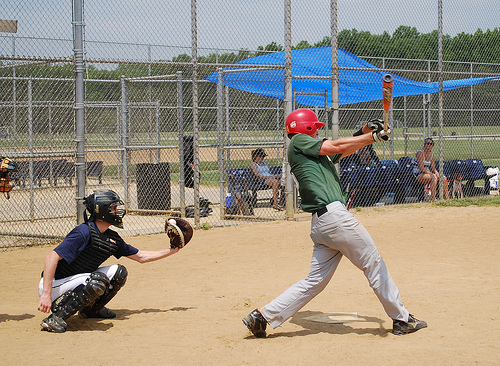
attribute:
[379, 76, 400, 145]
bat — short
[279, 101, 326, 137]
helmet — red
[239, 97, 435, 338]
man — batting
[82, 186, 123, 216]
helmet — black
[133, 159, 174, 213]
trash can — black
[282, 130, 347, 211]
jersey — green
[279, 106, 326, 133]
helmet — red